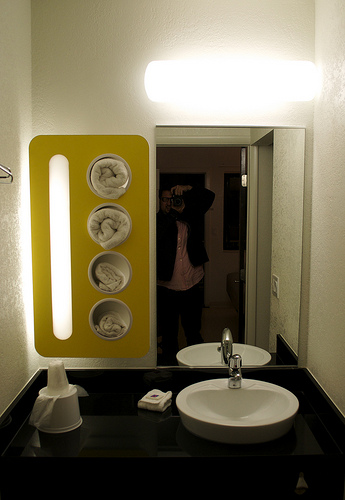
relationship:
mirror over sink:
[149, 119, 308, 366] [175, 372, 298, 449]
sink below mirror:
[176, 374, 301, 443] [149, 119, 308, 366]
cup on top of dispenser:
[47, 358, 69, 394] [28, 385, 90, 452]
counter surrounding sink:
[0, 361, 341, 498] [176, 374, 301, 443]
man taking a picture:
[156, 183, 216, 366] [2, 2, 343, 498]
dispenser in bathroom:
[28, 359, 88, 432] [5, 7, 333, 479]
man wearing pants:
[154, 183, 210, 362] [156, 285, 205, 363]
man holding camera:
[156, 183, 216, 366] [170, 194, 184, 208]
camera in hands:
[173, 192, 183, 208] [168, 180, 192, 198]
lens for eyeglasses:
[161, 196, 168, 200] [157, 194, 177, 204]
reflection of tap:
[212, 324, 236, 364] [225, 352, 246, 389]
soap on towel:
[148, 392, 163, 399] [136, 383, 171, 416]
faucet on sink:
[228, 354, 244, 390] [171, 366, 305, 438]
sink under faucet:
[176, 374, 301, 443] [224, 353, 246, 388]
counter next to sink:
[0, 396, 324, 473] [176, 374, 301, 443]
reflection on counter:
[102, 422, 177, 458] [4, 383, 336, 459]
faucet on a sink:
[228, 354, 242, 390] [161, 362, 306, 442]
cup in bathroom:
[39, 357, 73, 397] [5, 7, 333, 479]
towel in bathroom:
[136, 384, 172, 411] [3, 362, 343, 493]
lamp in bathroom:
[32, 158, 107, 344] [5, 7, 333, 479]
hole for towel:
[84, 152, 134, 203] [92, 154, 129, 202]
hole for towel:
[83, 201, 133, 249] [86, 208, 132, 244]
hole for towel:
[85, 247, 133, 296] [93, 261, 128, 288]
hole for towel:
[87, 296, 135, 345] [90, 311, 132, 339]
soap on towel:
[145, 386, 170, 401] [137, 388, 172, 413]